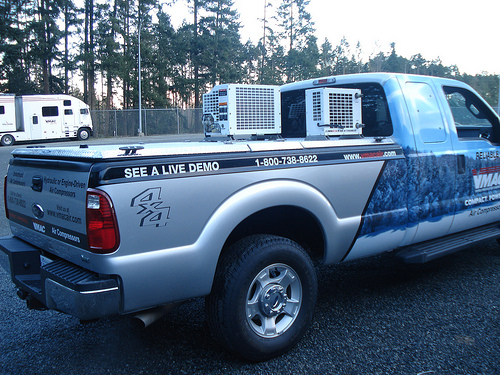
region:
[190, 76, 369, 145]
Small white machines on the truck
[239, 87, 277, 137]
Many small holes on the machine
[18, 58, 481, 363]
A truck parked in gravel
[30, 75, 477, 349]
A grey pickup truck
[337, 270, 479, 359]
Gravel beneath the truck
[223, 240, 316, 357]
A black rubber tire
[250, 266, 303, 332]
A silver hub cap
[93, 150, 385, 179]
Advertisements on the pickup truck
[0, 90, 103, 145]
A white RV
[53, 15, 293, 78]
Green trees in the distance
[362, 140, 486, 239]
tree scene painted on side of truck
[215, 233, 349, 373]
back tire on a truck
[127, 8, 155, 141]
light pole behind the truck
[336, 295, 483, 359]
gravel parking lot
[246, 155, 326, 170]
phone number on the side of the truck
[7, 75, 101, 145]
white tractor trailer behind the truck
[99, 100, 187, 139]
chain link fence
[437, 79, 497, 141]
open window of the truck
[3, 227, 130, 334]
back bumper of the truck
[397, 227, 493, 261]
step board on side of truck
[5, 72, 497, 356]
the 4x4 truck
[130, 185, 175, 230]
the 4x4 on the truck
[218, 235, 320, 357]
the back tire on the truck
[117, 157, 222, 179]
the word SEE on the side of the truck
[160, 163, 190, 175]
the word LIVE on the side of the truck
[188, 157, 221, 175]
the word DEMO on the side of the trick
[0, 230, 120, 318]
the back bumper of the truck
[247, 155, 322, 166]
the phone number on the side of the truck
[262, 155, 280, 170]
the numbers 800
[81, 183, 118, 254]
the tail light in the back of the truck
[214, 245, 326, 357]
black and chrome truck tire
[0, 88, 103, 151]
RV white with stripes truck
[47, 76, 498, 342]
grey with decals truck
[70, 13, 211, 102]
several green tall trees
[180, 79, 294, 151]
white with vent machine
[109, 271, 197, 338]
truck right side exhaust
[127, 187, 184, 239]
4 x 4 decal on truck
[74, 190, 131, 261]
rear red flasher on truck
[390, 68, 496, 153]
passanger windows of truck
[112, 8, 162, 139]
tall white street lamp by trees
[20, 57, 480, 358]
A pickup truck parked in gravel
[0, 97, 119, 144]
A white recreational vehicle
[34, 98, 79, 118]
Small black window on the RV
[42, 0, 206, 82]
Green trees in the distance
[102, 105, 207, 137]
A small metal fence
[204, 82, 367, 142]
Two white machines on the truck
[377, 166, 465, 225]
Trees painted on the truck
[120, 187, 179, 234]
The truck says "4x4"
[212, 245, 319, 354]
A black rubber truck tire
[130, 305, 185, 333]
A small metal muffler